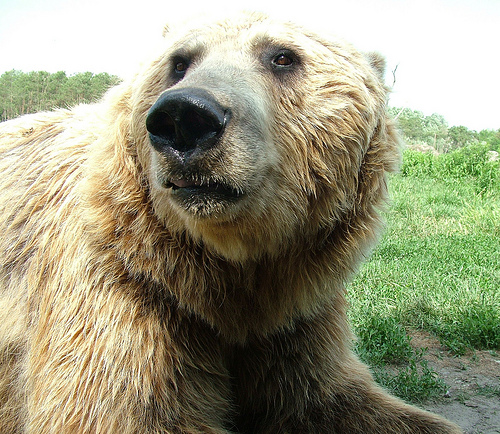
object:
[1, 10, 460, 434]
bear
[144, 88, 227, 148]
nose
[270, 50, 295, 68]
eye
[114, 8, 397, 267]
head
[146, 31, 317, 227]
face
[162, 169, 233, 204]
mouth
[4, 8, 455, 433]
hair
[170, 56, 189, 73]
eye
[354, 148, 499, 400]
grass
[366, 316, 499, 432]
dirt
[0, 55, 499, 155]
tree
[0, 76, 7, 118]
tree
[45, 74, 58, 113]
tree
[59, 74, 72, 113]
tree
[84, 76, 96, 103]
tree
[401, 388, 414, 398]
grass patch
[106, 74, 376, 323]
neck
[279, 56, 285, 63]
spot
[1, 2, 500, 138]
sky